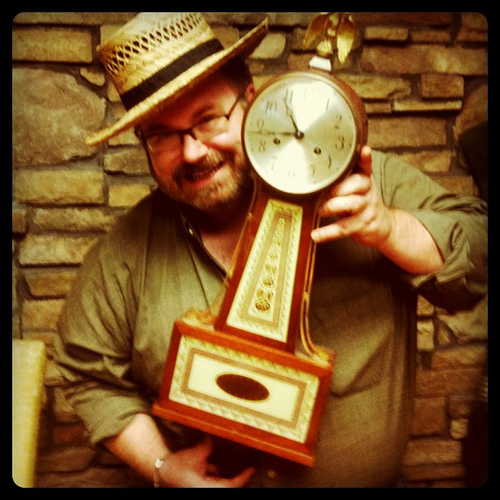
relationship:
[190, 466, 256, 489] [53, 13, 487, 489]
finger on person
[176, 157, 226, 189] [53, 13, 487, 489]
mouth on person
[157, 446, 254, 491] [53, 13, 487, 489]
hand of person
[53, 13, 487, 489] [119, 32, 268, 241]
person has head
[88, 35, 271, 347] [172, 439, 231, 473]
person has finger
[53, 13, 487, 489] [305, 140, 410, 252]
person has hand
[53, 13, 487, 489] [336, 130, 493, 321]
person has arm